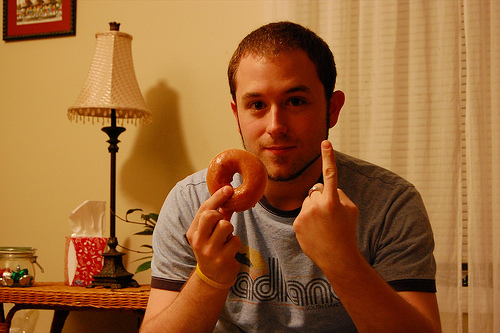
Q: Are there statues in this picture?
A: No, there are no statues.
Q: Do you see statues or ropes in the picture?
A: No, there are no statues or ropes.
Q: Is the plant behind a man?
A: Yes, the plant is behind a man.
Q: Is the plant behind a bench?
A: No, the plant is behind a man.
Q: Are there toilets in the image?
A: No, there are no toilets.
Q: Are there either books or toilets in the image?
A: No, there are no toilets or books.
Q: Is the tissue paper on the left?
A: Yes, the tissue paper is on the left of the image.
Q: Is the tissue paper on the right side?
A: No, the tissue paper is on the left of the image.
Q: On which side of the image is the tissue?
A: The tissue is on the left of the image.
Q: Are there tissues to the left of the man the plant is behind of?
A: Yes, there is a tissue to the left of the man.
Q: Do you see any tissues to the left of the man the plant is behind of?
A: Yes, there is a tissue to the left of the man.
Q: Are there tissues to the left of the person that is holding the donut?
A: Yes, there is a tissue to the left of the man.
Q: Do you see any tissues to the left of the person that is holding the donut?
A: Yes, there is a tissue to the left of the man.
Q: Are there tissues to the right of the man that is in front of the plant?
A: No, the tissue is to the left of the man.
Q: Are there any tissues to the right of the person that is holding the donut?
A: No, the tissue is to the left of the man.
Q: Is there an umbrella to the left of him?
A: No, there is a tissue to the left of the man.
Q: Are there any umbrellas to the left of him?
A: No, there is a tissue to the left of the man.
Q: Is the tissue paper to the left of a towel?
A: No, the tissue paper is to the left of the man.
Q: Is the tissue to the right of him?
A: No, the tissue is to the left of the man.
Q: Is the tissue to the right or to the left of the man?
A: The tissue is to the left of the man.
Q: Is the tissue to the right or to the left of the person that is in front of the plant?
A: The tissue is to the left of the man.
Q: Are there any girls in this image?
A: No, there are no girls.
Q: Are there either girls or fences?
A: No, there are no girls or fences.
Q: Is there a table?
A: Yes, there is a table.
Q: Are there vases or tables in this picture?
A: Yes, there is a table.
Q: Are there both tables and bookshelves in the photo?
A: No, there is a table but no bookshelves.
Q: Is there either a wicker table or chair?
A: Yes, there is a wicker table.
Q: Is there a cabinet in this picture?
A: No, there are no cabinets.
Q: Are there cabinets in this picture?
A: No, there are no cabinets.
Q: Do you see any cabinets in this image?
A: No, there are no cabinets.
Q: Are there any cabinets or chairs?
A: No, there are no cabinets or chairs.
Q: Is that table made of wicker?
A: Yes, the table is made of wicker.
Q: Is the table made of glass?
A: No, the table is made of wicker.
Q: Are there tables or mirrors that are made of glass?
A: No, there is a table but it is made of wicker.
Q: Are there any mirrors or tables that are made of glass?
A: No, there is a table but it is made of wicker.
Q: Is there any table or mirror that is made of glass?
A: No, there is a table but it is made of wicker.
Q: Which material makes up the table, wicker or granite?
A: The table is made of wicker.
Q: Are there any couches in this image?
A: No, there are no couches.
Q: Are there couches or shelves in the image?
A: No, there are no couches or shelves.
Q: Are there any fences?
A: No, there are no fences.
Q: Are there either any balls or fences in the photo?
A: No, there are no fences or balls.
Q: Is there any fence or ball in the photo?
A: No, there are no fences or balls.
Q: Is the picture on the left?
A: Yes, the picture is on the left of the image.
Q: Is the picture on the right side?
A: No, the picture is on the left of the image.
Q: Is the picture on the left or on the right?
A: The picture is on the left of the image.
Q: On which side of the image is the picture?
A: The picture is on the left of the image.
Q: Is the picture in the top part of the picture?
A: Yes, the picture is in the top of the image.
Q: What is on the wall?
A: The picture is on the wall.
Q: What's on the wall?
A: The picture is on the wall.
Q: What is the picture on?
A: The picture is on the wall.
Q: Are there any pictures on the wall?
A: Yes, there is a picture on the wall.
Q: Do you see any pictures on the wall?
A: Yes, there is a picture on the wall.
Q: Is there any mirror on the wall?
A: No, there is a picture on the wall.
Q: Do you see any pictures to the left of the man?
A: Yes, there is a picture to the left of the man.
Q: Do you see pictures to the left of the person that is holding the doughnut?
A: Yes, there is a picture to the left of the man.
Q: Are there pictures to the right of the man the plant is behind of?
A: No, the picture is to the left of the man.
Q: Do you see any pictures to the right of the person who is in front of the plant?
A: No, the picture is to the left of the man.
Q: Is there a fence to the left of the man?
A: No, there is a picture to the left of the man.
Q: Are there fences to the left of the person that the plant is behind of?
A: No, there is a picture to the left of the man.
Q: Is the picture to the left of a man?
A: Yes, the picture is to the left of a man.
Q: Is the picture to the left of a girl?
A: No, the picture is to the left of a man.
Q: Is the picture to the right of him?
A: No, the picture is to the left of the man.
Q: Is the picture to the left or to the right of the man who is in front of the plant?
A: The picture is to the left of the man.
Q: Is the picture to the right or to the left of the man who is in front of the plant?
A: The picture is to the left of the man.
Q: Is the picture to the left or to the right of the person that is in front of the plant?
A: The picture is to the left of the man.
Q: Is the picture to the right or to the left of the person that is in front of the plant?
A: The picture is to the left of the man.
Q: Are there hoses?
A: No, there are no hoses.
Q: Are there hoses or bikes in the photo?
A: No, there are no hoses or bikes.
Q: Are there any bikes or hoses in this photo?
A: No, there are no hoses or bikes.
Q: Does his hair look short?
A: Yes, the hair is short.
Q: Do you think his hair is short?
A: Yes, the hair is short.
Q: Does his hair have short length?
A: Yes, the hair is short.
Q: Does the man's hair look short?
A: Yes, the hair is short.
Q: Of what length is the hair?
A: The hair is short.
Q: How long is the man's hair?
A: The hair is short.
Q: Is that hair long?
A: No, the hair is short.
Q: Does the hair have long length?
A: No, the hair is short.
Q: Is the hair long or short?
A: The hair is short.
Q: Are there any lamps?
A: Yes, there is a lamp.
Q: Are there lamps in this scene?
A: Yes, there is a lamp.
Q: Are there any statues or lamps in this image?
A: Yes, there is a lamp.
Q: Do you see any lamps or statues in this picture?
A: Yes, there is a lamp.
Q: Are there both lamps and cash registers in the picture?
A: No, there is a lamp but no cash registers.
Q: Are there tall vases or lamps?
A: Yes, there is a tall lamp.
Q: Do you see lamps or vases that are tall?
A: Yes, the lamp is tall.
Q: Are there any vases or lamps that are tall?
A: Yes, the lamp is tall.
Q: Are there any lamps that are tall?
A: Yes, there is a tall lamp.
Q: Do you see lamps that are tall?
A: Yes, there is a tall lamp.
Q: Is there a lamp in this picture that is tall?
A: Yes, there is a lamp that is tall.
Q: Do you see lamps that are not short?
A: Yes, there is a tall lamp.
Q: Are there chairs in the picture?
A: No, there are no chairs.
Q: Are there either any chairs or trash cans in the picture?
A: No, there are no chairs or trash cans.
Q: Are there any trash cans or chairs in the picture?
A: No, there are no chairs or trash cans.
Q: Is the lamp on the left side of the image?
A: Yes, the lamp is on the left of the image.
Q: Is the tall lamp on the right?
A: No, the lamp is on the left of the image.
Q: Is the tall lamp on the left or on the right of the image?
A: The lamp is on the left of the image.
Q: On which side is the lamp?
A: The lamp is on the left of the image.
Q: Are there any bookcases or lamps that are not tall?
A: No, there is a lamp but it is tall.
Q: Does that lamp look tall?
A: Yes, the lamp is tall.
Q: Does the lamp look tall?
A: Yes, the lamp is tall.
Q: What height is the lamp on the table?
A: The lamp is tall.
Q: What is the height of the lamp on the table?
A: The lamp is tall.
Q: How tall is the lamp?
A: The lamp is tall.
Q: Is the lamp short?
A: No, the lamp is tall.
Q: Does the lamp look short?
A: No, the lamp is tall.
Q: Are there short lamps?
A: No, there is a lamp but it is tall.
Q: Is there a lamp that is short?
A: No, there is a lamp but it is tall.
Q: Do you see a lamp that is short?
A: No, there is a lamp but it is tall.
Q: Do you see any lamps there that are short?
A: No, there is a lamp but it is tall.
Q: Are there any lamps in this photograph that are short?
A: No, there is a lamp but it is tall.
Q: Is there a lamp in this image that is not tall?
A: No, there is a lamp but it is tall.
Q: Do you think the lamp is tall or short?
A: The lamp is tall.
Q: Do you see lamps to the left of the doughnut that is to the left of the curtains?
A: Yes, there is a lamp to the left of the donut.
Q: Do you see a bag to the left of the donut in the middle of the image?
A: No, there is a lamp to the left of the doughnut.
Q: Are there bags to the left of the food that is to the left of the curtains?
A: No, there is a lamp to the left of the doughnut.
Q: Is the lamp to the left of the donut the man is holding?
A: Yes, the lamp is to the left of the doughnut.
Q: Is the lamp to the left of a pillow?
A: No, the lamp is to the left of the doughnut.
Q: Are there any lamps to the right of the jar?
A: Yes, there is a lamp to the right of the jar.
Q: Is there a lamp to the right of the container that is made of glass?
A: Yes, there is a lamp to the right of the jar.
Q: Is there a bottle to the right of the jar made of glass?
A: No, there is a lamp to the right of the jar.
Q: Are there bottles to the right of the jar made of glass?
A: No, there is a lamp to the right of the jar.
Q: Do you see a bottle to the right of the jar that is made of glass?
A: No, there is a lamp to the right of the jar.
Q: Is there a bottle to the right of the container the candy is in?
A: No, there is a lamp to the right of the jar.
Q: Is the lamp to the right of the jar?
A: Yes, the lamp is to the right of the jar.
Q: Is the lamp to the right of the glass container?
A: Yes, the lamp is to the right of the jar.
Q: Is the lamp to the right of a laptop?
A: No, the lamp is to the right of the jar.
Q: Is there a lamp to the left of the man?
A: Yes, there is a lamp to the left of the man.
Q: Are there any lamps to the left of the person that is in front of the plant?
A: Yes, there is a lamp to the left of the man.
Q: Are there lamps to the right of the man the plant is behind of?
A: No, the lamp is to the left of the man.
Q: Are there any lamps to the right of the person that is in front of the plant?
A: No, the lamp is to the left of the man.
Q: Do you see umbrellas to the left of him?
A: No, there is a lamp to the left of the man.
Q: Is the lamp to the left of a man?
A: Yes, the lamp is to the left of a man.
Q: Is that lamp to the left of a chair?
A: No, the lamp is to the left of a man.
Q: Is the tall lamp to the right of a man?
A: No, the lamp is to the left of a man.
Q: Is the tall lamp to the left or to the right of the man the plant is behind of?
A: The lamp is to the left of the man.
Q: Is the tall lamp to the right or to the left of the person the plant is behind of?
A: The lamp is to the left of the man.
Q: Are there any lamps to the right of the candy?
A: Yes, there is a lamp to the right of the candy.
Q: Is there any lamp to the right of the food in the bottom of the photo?
A: Yes, there is a lamp to the right of the candy.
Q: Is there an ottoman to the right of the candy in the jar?
A: No, there is a lamp to the right of the candy.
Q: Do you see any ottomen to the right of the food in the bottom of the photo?
A: No, there is a lamp to the right of the candy.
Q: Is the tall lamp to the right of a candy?
A: Yes, the lamp is to the right of a candy.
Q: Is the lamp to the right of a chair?
A: No, the lamp is to the right of a candy.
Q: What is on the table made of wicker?
A: The lamp is on the table.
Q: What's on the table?
A: The lamp is on the table.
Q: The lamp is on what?
A: The lamp is on the table.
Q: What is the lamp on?
A: The lamp is on the table.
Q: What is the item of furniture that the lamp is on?
A: The piece of furniture is a table.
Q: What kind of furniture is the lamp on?
A: The lamp is on the table.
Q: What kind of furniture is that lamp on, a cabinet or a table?
A: The lamp is on a table.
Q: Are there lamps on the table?
A: Yes, there is a lamp on the table.